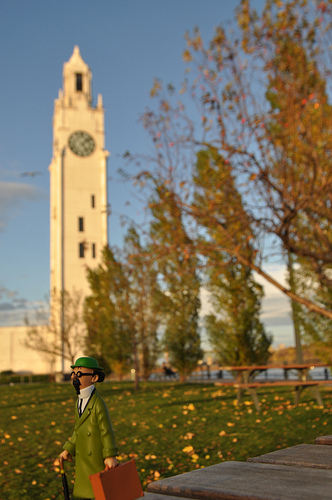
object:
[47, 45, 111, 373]
clock tower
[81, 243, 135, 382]
tree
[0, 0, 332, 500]
fall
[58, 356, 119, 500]
man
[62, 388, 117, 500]
coat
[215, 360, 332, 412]
bench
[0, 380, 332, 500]
grass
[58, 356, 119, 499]
toy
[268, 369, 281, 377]
water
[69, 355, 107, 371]
hat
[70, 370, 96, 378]
glasses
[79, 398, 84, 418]
tie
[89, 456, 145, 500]
suitcase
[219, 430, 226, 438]
leaves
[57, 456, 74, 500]
umbrella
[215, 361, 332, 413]
table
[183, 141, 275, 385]
trees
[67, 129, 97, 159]
clock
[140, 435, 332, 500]
sidewalk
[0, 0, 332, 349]
sky